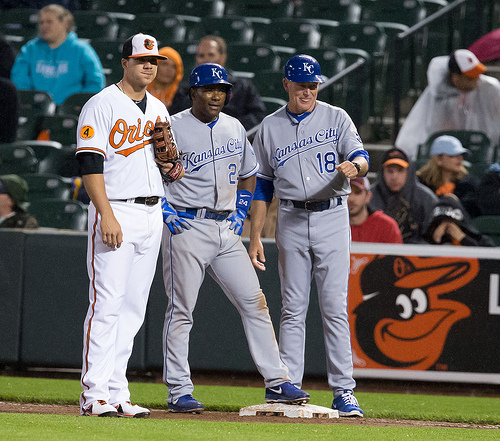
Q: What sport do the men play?
A: Baseball.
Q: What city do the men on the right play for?
A: Kansas City.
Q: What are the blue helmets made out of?
A: Plastic.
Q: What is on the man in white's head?
A: Baseball cap.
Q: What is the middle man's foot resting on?
A: Base plate.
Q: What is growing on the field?
A: Grass.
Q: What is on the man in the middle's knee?
A: Clay.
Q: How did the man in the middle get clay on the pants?
A: Sliding.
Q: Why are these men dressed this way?
A: They are wearing uniforms to play baseball in.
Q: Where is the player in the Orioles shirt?
A: To the left of the two players, wearing Kansas city uniforms.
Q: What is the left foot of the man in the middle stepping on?
A: A baseball base.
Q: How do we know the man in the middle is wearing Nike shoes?
A: Because of the white check on the side of the shoe.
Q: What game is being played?
A: Baseball.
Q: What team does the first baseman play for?
A: Orioles.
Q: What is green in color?
A: The grass.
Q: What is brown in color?
A: The dirt.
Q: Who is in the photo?
A: Some people.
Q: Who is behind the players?
A: The crowd.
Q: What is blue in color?
A: The helmet.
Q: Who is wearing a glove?
A: The player.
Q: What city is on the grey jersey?
A: Kansas City.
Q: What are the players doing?
A: Standing.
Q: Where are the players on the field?
A: Three.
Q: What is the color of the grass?
A: Green.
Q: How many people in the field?
A: Three.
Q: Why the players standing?
A: They are looking someone.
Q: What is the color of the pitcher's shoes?
A: White.